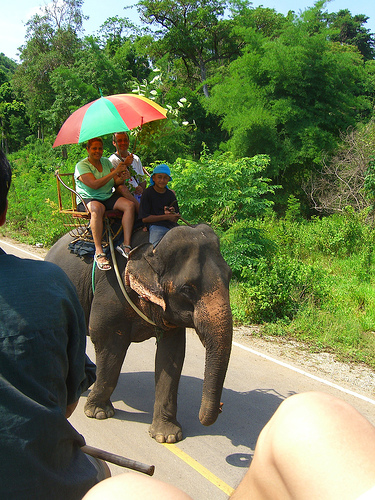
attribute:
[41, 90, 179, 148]
umbrella — red, multi colored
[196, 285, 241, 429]
trunk — long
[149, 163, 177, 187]
cap — blue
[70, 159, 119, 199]
t-shirt — green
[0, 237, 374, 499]
ground — painted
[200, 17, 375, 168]
tree — green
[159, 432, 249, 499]
line — yellow